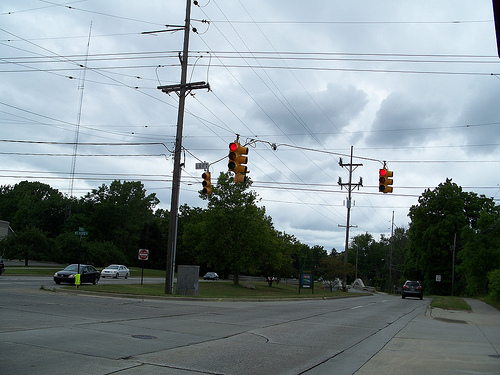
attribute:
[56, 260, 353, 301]
grass — green , some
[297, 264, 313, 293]
sign — for passing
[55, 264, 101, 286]
car — one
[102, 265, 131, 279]
car — one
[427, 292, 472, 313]
grass area — grassy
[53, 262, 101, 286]
car — black , running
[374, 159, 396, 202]
signal — yellow, traffic , light , one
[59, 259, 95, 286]
car — one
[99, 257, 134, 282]
car — one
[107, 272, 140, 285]
road — one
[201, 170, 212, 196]
traffic signal — for left turn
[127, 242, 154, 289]
sign — for traffic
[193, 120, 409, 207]
street lights — street , some, yellow , grouped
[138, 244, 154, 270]
sign — "do not enter"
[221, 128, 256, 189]
signal — yellow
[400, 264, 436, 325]
car — black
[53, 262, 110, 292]
car — driving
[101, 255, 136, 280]
car — white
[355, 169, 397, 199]
light — red, traffic , illuminated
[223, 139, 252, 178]
light — one, red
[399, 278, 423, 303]
suv — dark-colored, running, one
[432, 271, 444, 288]
traffic sign — one, white, street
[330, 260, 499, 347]
sidewalk — side, one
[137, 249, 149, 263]
sign — one, street 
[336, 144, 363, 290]
telephone pole — telephone , one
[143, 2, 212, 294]
telephone pole — one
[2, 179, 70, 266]
round tree — round , large 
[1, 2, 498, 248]
clouds — some, dark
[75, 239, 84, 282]
post — street , sign